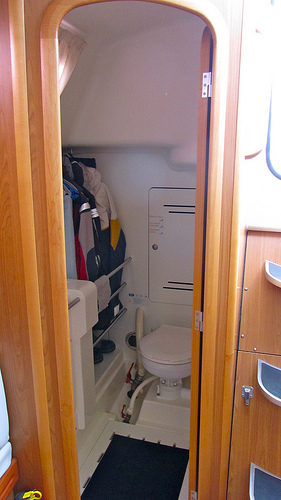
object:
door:
[188, 20, 210, 498]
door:
[237, 232, 279, 356]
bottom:
[152, 379, 182, 402]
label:
[146, 211, 165, 235]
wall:
[74, 152, 195, 367]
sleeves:
[63, 195, 77, 278]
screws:
[202, 92, 205, 97]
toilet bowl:
[138, 323, 192, 383]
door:
[40, 0, 216, 499]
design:
[109, 219, 119, 249]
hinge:
[201, 73, 210, 99]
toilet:
[139, 185, 196, 403]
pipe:
[129, 311, 146, 395]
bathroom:
[53, 1, 212, 499]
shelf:
[94, 346, 120, 386]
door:
[146, 188, 199, 308]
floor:
[79, 420, 188, 499]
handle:
[239, 383, 253, 408]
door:
[223, 349, 279, 498]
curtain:
[56, 33, 87, 96]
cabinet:
[220, 349, 279, 499]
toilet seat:
[138, 322, 193, 364]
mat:
[76, 433, 192, 499]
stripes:
[78, 201, 89, 211]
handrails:
[90, 256, 134, 349]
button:
[242, 284, 249, 292]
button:
[250, 346, 261, 351]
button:
[252, 346, 258, 351]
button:
[239, 331, 246, 339]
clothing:
[79, 182, 103, 280]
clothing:
[68, 185, 81, 199]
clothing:
[73, 189, 99, 281]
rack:
[63, 149, 80, 173]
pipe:
[125, 376, 158, 416]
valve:
[120, 402, 126, 417]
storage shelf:
[264, 259, 280, 288]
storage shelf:
[256, 357, 281, 410]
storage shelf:
[247, 211, 281, 460]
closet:
[62, 146, 133, 433]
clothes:
[61, 191, 78, 279]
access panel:
[148, 187, 196, 305]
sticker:
[126, 291, 148, 306]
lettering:
[128, 291, 144, 298]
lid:
[137, 322, 193, 361]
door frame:
[39, 1, 81, 499]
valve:
[124, 361, 135, 383]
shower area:
[58, 0, 212, 499]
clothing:
[86, 167, 125, 317]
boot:
[92, 346, 103, 363]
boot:
[92, 333, 114, 353]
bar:
[95, 256, 132, 288]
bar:
[98, 281, 128, 319]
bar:
[93, 307, 126, 346]